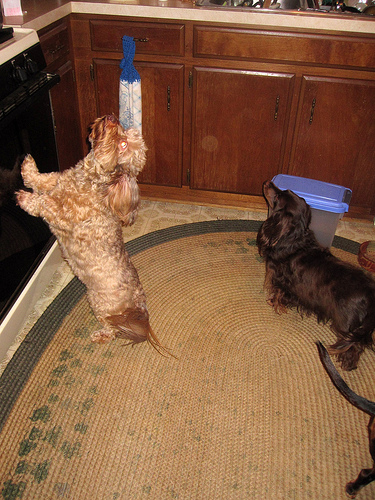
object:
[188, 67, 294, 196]
door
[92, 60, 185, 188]
door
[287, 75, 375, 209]
door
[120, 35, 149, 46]
holder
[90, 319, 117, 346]
legs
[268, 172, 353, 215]
lid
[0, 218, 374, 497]
rug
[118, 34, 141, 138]
towel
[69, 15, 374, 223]
cabinets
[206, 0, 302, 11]
sink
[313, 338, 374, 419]
tail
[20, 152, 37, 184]
paw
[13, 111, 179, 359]
dog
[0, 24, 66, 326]
stove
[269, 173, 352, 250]
container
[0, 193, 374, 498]
floor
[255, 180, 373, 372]
dog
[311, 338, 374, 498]
dog